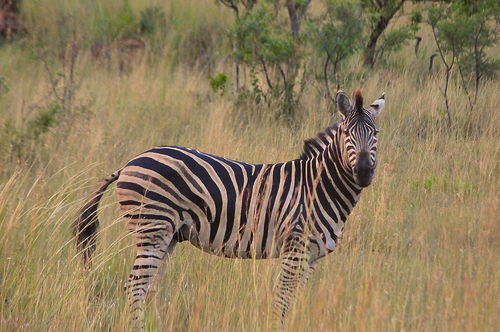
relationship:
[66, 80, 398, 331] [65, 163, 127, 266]
zebra has tail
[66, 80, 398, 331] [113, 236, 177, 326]
zebra seen back legs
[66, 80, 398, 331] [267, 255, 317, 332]
zebra seen front legs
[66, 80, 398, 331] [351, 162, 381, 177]
zebra seen nose and nostrils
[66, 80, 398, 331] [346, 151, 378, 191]
zebra seen mouth area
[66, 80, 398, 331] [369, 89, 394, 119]
zebra seen left ear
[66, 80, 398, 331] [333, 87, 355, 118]
zebra seen right ear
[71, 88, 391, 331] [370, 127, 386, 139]
zebra seen left eye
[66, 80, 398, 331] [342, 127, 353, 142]
zebra seen right eye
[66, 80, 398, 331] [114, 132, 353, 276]
zebra has stripes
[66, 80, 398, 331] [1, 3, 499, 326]
zebra on plain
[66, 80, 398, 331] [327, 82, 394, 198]
zebra seen head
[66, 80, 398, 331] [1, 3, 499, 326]
zebra in wild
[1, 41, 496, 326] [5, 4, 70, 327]
grass in back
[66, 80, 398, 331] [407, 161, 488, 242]
zebra looking camera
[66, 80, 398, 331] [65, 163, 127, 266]
zebra seen tail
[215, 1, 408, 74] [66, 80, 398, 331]
tree behind zebra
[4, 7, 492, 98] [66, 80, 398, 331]
bushes behind zebra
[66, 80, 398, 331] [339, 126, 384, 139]
zebra seen two eyes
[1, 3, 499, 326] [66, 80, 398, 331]
scene with a zebra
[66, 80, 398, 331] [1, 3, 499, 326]
zebra standing in field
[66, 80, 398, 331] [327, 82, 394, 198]
zebra seen a head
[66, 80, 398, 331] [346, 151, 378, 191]
zebra seen a nose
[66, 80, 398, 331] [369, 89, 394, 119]
zebra has left ear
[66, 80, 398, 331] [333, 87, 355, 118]
zebra has right ear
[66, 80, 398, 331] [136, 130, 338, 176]
zebra seen backside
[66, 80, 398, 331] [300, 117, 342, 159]
zebra seen mane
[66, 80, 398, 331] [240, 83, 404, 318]
zebra seen front half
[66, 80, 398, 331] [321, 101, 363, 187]
zebra seen sideview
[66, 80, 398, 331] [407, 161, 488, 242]
zebra looking at camera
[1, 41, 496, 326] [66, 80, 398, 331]
grass color tan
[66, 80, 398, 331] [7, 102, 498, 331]
zebra in foreground